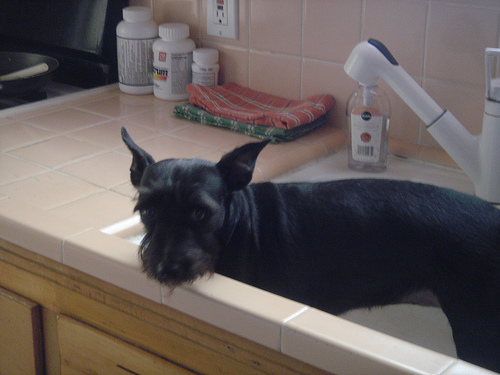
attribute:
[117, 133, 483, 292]
dog — black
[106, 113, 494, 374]
dog — black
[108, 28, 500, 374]
sink — white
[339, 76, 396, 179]
soap — clear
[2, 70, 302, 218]
counter — cream, tiled, beige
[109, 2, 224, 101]
bottles — white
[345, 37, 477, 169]
faucet — plastic, white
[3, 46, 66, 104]
pot — black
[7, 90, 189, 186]
tile — red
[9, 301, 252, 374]
cabinet — brown, wooden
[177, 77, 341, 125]
towel — striped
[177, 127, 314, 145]
towel — green